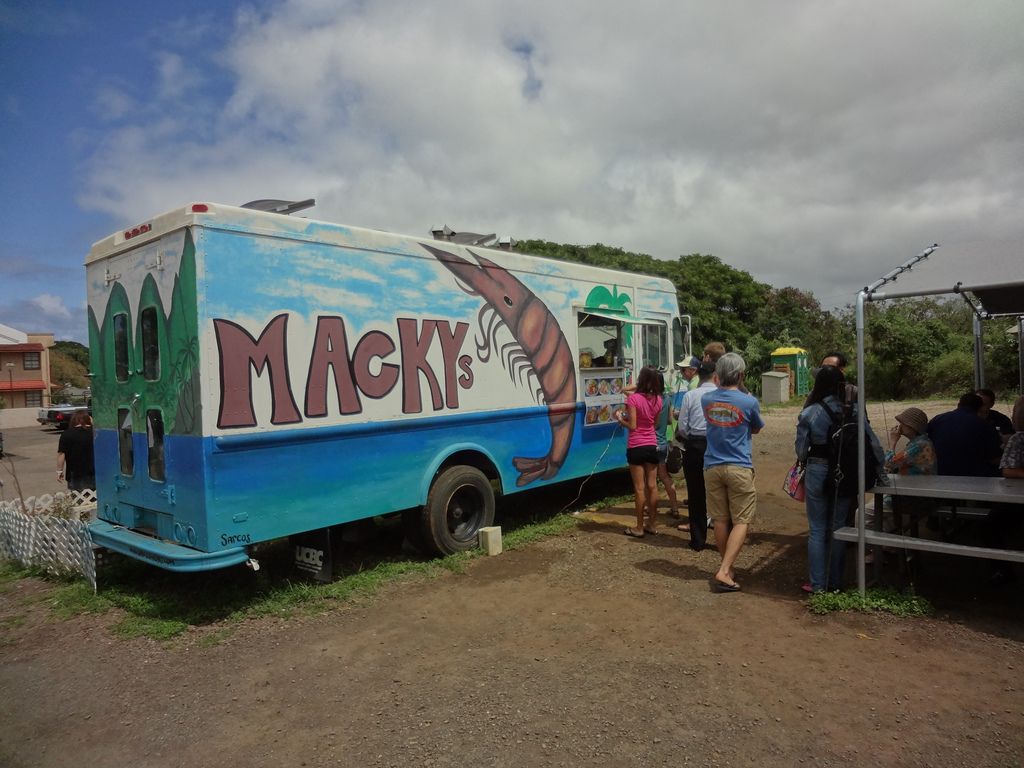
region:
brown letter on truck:
[214, 318, 313, 433]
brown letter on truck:
[300, 315, 362, 413]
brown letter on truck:
[348, 329, 396, 399]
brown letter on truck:
[394, 313, 445, 416]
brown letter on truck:
[426, 309, 468, 411]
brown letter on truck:
[461, 351, 477, 393]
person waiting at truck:
[622, 366, 662, 535]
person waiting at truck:
[672, 358, 724, 549]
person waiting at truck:
[698, 348, 766, 590]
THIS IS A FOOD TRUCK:
[55, 178, 724, 605]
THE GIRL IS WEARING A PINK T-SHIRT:
[615, 390, 669, 451]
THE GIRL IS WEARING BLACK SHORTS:
[621, 440, 661, 476]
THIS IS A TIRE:
[408, 446, 522, 579]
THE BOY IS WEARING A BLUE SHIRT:
[689, 380, 772, 463]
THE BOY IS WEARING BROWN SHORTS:
[694, 457, 768, 540]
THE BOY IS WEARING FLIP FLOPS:
[702, 563, 748, 608]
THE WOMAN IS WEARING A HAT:
[887, 399, 935, 444]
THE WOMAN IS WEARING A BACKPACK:
[800, 386, 874, 511]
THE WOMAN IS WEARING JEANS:
[789, 448, 867, 601]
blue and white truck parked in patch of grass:
[70, 196, 703, 580]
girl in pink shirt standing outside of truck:
[604, 358, 674, 549]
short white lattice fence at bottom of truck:
[2, 483, 110, 601]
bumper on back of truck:
[78, 505, 255, 582]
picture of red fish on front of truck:
[408, 237, 587, 494]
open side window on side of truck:
[566, 295, 669, 384]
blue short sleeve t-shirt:
[692, 380, 768, 478]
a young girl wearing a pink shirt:
[624, 389, 672, 438]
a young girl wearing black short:
[626, 439, 668, 478]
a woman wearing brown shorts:
[700, 465, 771, 533]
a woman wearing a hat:
[889, 401, 941, 443]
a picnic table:
[844, 459, 1021, 593]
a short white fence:
[5, 499, 105, 602]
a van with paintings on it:
[67, 203, 697, 614]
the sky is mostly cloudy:
[254, 45, 804, 322]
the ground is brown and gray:
[275, 628, 535, 753]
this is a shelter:
[813, 259, 1000, 560]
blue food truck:
[38, 122, 687, 557]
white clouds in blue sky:
[359, 57, 464, 179]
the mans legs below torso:
[700, 470, 764, 569]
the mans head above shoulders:
[709, 353, 755, 391]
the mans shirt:
[697, 386, 759, 475]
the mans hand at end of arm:
[664, 408, 677, 432]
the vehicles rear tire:
[402, 443, 508, 561]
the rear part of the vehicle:
[27, 184, 240, 592]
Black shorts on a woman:
[625, 442, 663, 468]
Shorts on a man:
[702, 461, 761, 528]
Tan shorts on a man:
[702, 459, 761, 535]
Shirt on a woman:
[619, 392, 664, 450]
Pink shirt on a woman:
[618, 389, 666, 454]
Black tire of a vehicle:
[417, 456, 503, 562]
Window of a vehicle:
[138, 304, 164, 384]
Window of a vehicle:
[138, 407, 176, 494]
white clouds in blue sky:
[0, 4, 1018, 340]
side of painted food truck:
[90, 196, 691, 571]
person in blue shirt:
[699, 354, 761, 590]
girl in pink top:
[614, 362, 665, 539]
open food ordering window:
[574, 311, 661, 395]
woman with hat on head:
[886, 407, 943, 475]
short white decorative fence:
[0, 489, 99, 573]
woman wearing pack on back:
[794, 365, 880, 593]